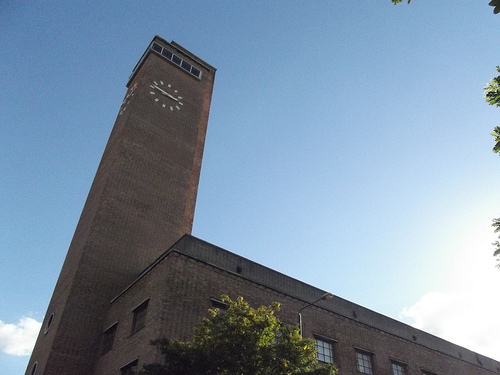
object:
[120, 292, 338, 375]
leaves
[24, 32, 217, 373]
tower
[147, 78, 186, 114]
display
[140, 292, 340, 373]
tree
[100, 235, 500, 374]
building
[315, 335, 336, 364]
windows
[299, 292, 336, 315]
lamp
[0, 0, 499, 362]
sky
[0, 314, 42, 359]
cloud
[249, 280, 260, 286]
bricks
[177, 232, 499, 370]
roof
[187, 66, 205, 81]
window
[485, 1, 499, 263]
tree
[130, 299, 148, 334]
windows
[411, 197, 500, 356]
sun glare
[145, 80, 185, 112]
clock hands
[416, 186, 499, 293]
sunlight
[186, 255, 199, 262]
brick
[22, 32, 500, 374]
distance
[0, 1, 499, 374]
miles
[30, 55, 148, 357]
sides